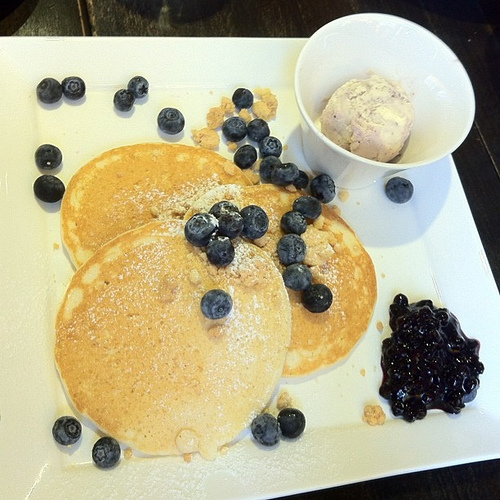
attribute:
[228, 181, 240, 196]
sugar — powdered 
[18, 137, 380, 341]
food — breakfast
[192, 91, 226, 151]
sugar — Brown 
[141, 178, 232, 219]
sugar — white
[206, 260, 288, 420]
sugar — powered 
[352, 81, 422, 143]
butter — blueberry flavored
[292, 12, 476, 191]
dish — white 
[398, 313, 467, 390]
blueberries — cooked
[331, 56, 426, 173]
butter — a side of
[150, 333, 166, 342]
holes — small 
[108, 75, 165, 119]
berries — blue 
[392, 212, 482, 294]
plate — small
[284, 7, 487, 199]
cup — white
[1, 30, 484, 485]
plate — square, white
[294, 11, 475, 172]
bowl — round , white 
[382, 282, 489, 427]
sauce — blueberry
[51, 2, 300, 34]
boards — black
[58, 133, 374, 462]
pancakes — blueberry